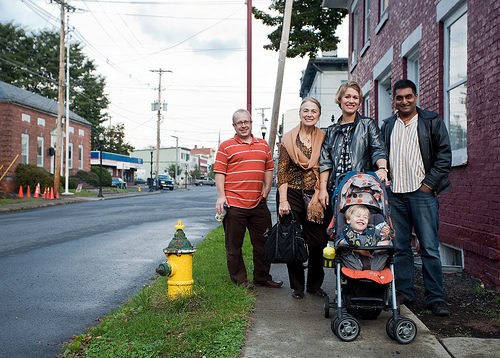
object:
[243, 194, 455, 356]
sidewalk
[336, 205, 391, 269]
toddler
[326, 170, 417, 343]
stroller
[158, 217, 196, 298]
fire hydrant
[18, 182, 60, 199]
cluster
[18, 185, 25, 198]
cones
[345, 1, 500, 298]
building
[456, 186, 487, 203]
brick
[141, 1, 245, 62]
power lines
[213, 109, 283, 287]
man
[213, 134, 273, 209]
shirt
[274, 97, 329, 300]
woman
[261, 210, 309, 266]
bag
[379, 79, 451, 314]
man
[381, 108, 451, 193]
jacket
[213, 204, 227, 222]
bottle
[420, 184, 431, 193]
hand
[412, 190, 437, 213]
pocket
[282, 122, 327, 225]
scarf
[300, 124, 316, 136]
neck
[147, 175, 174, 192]
truck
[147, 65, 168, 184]
pole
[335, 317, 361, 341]
wheel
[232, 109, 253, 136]
head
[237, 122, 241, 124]
eye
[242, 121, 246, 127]
nose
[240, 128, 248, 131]
mouth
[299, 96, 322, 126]
head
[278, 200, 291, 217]
hand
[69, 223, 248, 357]
grass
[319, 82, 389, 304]
woman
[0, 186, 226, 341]
city street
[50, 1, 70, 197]
pole